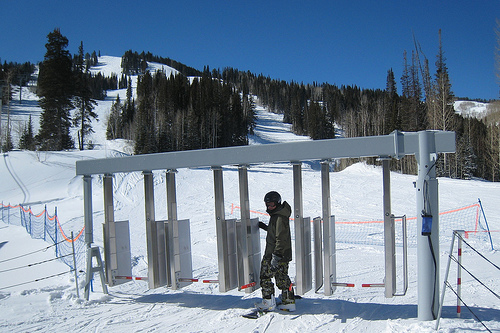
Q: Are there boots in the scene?
A: Yes, there are boots.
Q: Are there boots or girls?
A: Yes, there are boots.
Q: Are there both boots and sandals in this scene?
A: No, there are boots but no sandals.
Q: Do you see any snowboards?
A: Yes, there is a snowboard.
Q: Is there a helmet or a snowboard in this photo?
A: Yes, there is a snowboard.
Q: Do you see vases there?
A: No, there are no vases.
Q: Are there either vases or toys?
A: No, there are no vases or toys.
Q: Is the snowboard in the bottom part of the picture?
A: Yes, the snowboard is in the bottom of the image.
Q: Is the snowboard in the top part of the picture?
A: No, the snowboard is in the bottom of the image.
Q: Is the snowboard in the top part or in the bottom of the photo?
A: The snowboard is in the bottom of the image.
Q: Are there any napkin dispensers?
A: No, there are no napkin dispensers.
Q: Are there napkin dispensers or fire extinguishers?
A: No, there are no napkin dispensers or fire extinguishers.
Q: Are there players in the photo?
A: No, there are no players.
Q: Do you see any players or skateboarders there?
A: No, there are no players or skateboarders.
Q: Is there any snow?
A: Yes, there is snow.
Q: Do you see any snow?
A: Yes, there is snow.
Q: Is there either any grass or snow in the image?
A: Yes, there is snow.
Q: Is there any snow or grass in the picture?
A: Yes, there is snow.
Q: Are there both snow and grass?
A: No, there is snow but no grass.